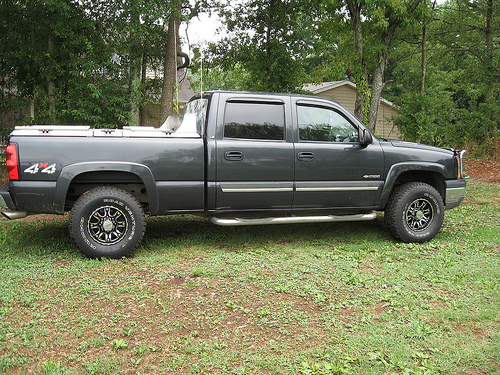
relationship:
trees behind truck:
[7, 7, 460, 90] [38, 110, 392, 215]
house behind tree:
[295, 80, 405, 141] [250, 1, 428, 172]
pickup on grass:
[5, 90, 466, 257] [1, 213, 496, 371]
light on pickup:
[5, 145, 18, 180] [5, 17, 468, 259]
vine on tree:
[345, 58, 372, 126] [144, 1, 196, 125]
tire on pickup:
[385, 184, 445, 251] [0, 90, 470, 260]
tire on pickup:
[62, 186, 154, 264] [0, 90, 470, 260]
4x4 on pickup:
[23, 160, 61, 178] [0, 90, 470, 260]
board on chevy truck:
[218, 204, 403, 234] [2, 86, 467, 260]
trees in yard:
[0, 0, 500, 160] [12, 247, 492, 348]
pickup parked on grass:
[0, 90, 470, 260] [0, 175, 496, 374]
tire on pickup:
[384, 181, 445, 244] [0, 90, 470, 260]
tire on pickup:
[67, 186, 148, 261] [0, 90, 470, 260]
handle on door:
[298, 149, 314, 161] [290, 95, 387, 206]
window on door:
[219, 92, 287, 142] [218, 97, 294, 216]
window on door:
[289, 100, 359, 154] [299, 96, 383, 219]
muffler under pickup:
[0, 207, 22, 225] [0, 90, 470, 260]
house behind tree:
[324, 73, 412, 153] [339, 1, 419, 115]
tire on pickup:
[67, 186, 148, 261] [22, 83, 479, 254]